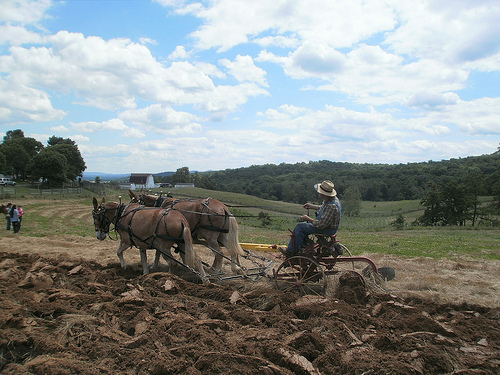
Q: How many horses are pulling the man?
A: Two.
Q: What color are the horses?
A: Light brown.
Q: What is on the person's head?
A: Hat.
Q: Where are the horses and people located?
A: Field.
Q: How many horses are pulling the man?
A: Two.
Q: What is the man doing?
A: Plowing.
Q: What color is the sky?
A: Blue.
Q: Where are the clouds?
A: Sky.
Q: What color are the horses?
A: Brown.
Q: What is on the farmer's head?
A: Straw hat.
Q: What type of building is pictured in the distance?
A: Barn.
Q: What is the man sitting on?
A: Plow.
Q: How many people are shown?
A: Four.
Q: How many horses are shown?
A: 2.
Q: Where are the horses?
A: Dirt field.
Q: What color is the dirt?
A: Brown.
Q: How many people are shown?
A: 4.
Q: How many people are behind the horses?
A: 1.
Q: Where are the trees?
A: Background.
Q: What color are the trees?
A: Green.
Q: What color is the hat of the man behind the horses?
A: White.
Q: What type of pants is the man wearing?
A: Overalls.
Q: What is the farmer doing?
A: Plowing.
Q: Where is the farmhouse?
A: In the back.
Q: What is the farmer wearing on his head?
A: A straw hat.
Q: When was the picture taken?
A: Daytime.